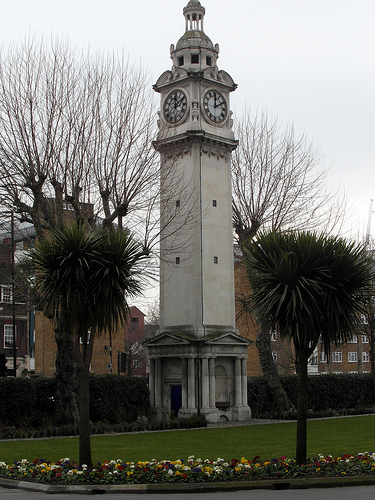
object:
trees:
[14, 215, 146, 468]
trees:
[240, 226, 374, 464]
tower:
[141, 0, 255, 423]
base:
[139, 328, 255, 424]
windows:
[175, 199, 181, 207]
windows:
[175, 255, 180, 265]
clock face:
[200, 85, 230, 127]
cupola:
[183, 0, 206, 32]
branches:
[230, 105, 349, 240]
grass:
[0, 411, 374, 474]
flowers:
[0, 449, 375, 485]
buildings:
[233, 242, 374, 376]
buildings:
[0, 192, 131, 377]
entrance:
[168, 381, 184, 422]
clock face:
[161, 87, 189, 127]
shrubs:
[0, 373, 151, 439]